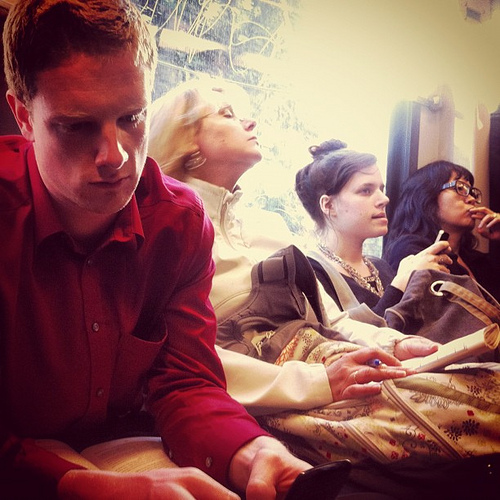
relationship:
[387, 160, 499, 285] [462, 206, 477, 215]
woman has mouth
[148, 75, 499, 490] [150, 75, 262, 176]
lady resting head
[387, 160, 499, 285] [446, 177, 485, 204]
woman wearing glasses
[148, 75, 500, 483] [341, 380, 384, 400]
lady sitting finger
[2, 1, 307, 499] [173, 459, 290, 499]
person has finger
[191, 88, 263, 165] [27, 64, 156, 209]
face of person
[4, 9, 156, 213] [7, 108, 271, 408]
face of person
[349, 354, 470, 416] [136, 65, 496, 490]
finger of person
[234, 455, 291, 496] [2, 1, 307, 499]
finger of person